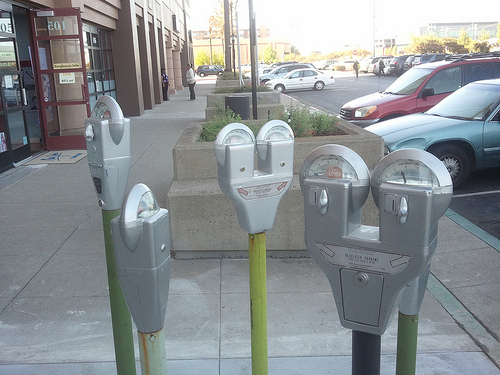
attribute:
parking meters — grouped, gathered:
[78, 91, 459, 375]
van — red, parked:
[334, 49, 499, 130]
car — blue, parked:
[362, 75, 499, 197]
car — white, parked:
[263, 66, 338, 96]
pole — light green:
[244, 231, 273, 374]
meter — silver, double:
[298, 141, 456, 338]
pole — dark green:
[100, 205, 139, 374]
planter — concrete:
[165, 112, 389, 266]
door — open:
[13, 5, 93, 157]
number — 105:
[45, 17, 68, 35]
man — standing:
[350, 58, 363, 81]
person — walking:
[375, 58, 388, 81]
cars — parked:
[256, 47, 500, 190]